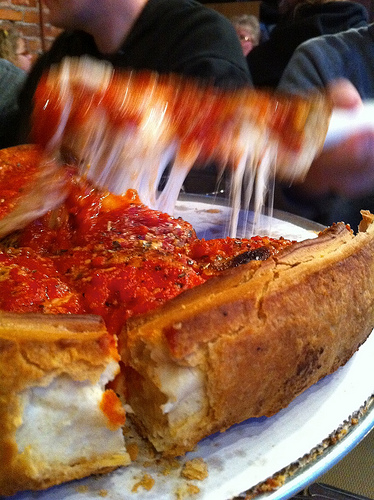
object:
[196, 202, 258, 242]
shadow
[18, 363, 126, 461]
cheese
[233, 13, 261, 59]
head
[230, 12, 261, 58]
person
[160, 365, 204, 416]
cheese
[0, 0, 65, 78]
wall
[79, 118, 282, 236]
cheese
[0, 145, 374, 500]
melted cheese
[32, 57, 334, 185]
pizza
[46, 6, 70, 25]
chin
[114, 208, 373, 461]
bread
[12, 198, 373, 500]
plate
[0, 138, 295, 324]
red sauce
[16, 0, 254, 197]
man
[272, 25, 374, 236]
man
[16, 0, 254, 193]
shirt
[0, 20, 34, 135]
woman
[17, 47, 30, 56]
glasses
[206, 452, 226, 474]
stains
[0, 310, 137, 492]
bread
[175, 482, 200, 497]
trimming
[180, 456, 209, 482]
crumbs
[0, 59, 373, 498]
pizza